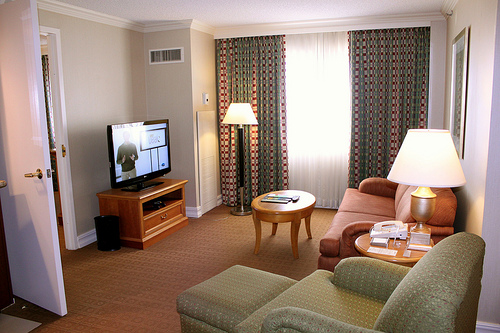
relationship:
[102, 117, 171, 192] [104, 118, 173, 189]
tv with housing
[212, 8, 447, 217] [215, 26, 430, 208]
window covered by curtain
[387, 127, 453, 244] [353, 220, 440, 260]
lamp sitting on a table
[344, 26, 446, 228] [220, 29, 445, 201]
curtains on window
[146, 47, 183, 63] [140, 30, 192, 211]
vent in wall